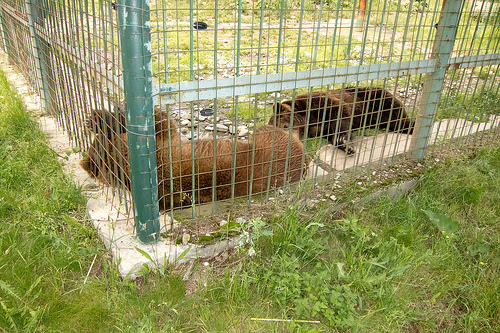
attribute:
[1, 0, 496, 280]
cage — square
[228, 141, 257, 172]
square — metal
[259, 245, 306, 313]
weed — green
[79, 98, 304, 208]
bear — brown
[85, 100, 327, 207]
bear — brown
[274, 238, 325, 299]
weed — green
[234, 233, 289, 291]
weed — green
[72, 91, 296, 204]
bear — brown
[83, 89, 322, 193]
bear — brown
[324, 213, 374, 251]
weed — green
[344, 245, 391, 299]
weed — green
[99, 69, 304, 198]
bear — brown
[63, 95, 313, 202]
bear — brown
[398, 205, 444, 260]
weed — green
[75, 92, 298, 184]
bear — brown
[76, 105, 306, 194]
bear — brown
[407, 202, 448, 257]
weed — green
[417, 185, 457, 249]
weed — green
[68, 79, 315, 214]
bear — brown